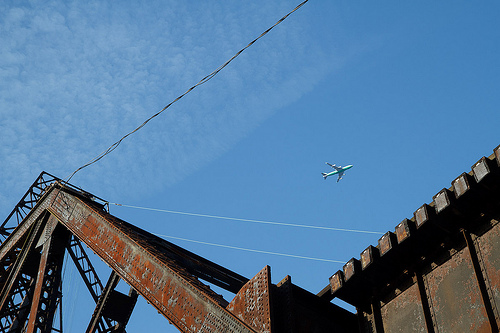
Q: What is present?
A: A plane.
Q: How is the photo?
A: Clear.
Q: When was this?
A: Daytime.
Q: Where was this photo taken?
A: On a bridge.